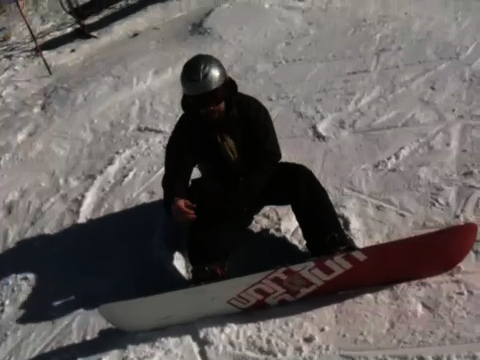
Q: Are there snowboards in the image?
A: Yes, there is a snowboard.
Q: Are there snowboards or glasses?
A: Yes, there is a snowboard.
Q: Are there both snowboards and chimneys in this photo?
A: No, there is a snowboard but no chimneys.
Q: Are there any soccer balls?
A: No, there are no soccer balls.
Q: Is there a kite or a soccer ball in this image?
A: No, there are no soccer balls or kites.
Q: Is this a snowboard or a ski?
A: This is a snowboard.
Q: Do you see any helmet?
A: Yes, there is a helmet.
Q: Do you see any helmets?
A: Yes, there is a helmet.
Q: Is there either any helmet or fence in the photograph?
A: Yes, there is a helmet.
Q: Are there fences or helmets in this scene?
A: Yes, there is a helmet.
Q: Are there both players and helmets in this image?
A: No, there is a helmet but no players.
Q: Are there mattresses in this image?
A: No, there are no mattresses.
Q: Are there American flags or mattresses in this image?
A: No, there are no mattresses or American flags.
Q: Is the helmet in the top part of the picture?
A: Yes, the helmet is in the top of the image.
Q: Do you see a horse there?
A: No, there are no horses.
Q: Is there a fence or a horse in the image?
A: No, there are no horses or fences.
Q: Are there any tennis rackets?
A: No, there are no tennis rackets.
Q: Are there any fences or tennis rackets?
A: No, there are no tennis rackets or fences.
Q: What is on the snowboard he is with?
A: The logo is on the snowboard.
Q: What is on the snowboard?
A: The logo is on the snowboard.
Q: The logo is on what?
A: The logo is on the snowboard.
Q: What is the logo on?
A: The logo is on the snowboard.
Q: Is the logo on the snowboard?
A: Yes, the logo is on the snowboard.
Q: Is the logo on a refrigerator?
A: No, the logo is on the snowboard.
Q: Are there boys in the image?
A: No, there are no boys.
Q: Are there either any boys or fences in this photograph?
A: No, there are no boys or fences.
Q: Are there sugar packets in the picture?
A: No, there are no sugar packets.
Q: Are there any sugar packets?
A: No, there are no sugar packets.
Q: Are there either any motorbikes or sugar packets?
A: No, there are no sugar packets or motorbikes.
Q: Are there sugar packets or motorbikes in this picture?
A: No, there are no sugar packets or motorbikes.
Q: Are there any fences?
A: No, there are no fences.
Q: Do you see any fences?
A: No, there are no fences.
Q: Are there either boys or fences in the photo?
A: No, there are no fences or boys.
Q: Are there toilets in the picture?
A: No, there are no toilets.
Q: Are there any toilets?
A: No, there are no toilets.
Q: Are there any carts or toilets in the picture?
A: No, there are no toilets or carts.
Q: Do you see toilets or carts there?
A: No, there are no toilets or carts.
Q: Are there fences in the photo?
A: No, there are no fences.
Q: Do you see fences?
A: No, there are no fences.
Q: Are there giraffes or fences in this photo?
A: No, there are no fences or giraffes.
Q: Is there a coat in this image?
A: Yes, there is a coat.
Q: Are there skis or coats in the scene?
A: Yes, there is a coat.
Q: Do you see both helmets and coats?
A: Yes, there are both a coat and a helmet.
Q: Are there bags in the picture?
A: No, there are no bags.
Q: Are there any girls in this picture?
A: No, there are no girls.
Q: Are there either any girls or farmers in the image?
A: No, there are no girls or farmers.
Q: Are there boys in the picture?
A: No, there are no boys.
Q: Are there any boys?
A: No, there are no boys.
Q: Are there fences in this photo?
A: No, there are no fences.